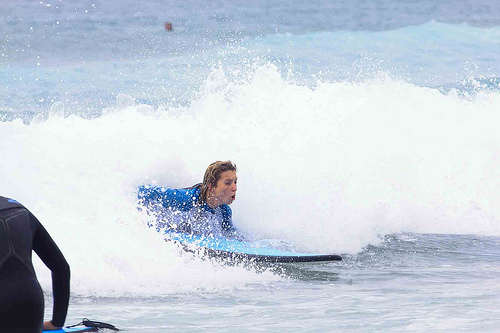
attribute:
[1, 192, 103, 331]
wetsuit — black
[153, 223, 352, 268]
surfboard — blue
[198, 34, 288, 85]
splashes — white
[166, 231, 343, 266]
surfboard — blue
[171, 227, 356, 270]
surfboard — bordered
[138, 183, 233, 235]
shirt — blue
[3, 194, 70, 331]
wetsuit — black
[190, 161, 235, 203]
hair — brown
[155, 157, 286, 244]
woman — blonde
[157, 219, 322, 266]
surfboard — blue, black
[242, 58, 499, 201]
spray — white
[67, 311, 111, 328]
rope — black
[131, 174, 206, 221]
shirt — blue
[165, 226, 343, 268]
surfboard — blue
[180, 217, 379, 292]
surfboard — blue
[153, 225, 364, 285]
surfboard — blue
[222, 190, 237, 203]
mouth — open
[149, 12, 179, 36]
object — brown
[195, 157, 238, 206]
hair — short